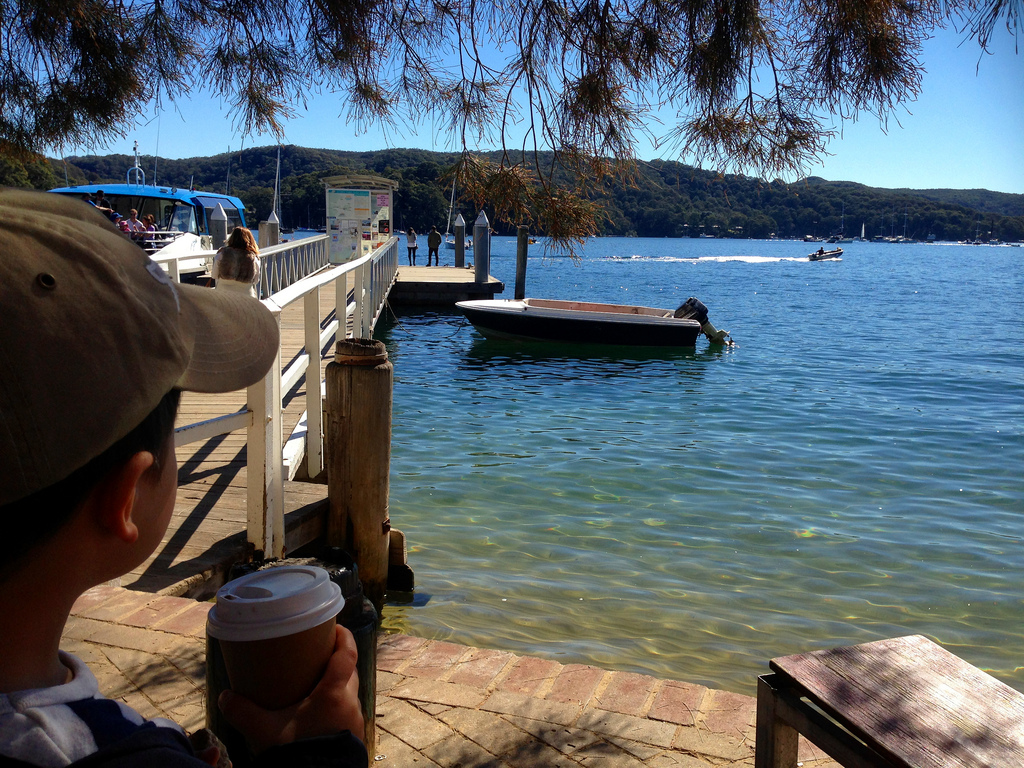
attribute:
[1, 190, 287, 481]
cap — baseball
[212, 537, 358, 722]
cup — coffee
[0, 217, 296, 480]
cap — brown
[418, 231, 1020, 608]
water — dark blue, dark, blue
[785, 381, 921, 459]
ripples — blue, dark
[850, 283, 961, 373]
ripples — dark, blue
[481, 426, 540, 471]
ripples — blue, dark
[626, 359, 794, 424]
ripples — dark, blue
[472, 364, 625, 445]
ripples — blue, dark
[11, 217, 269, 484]
hat — faded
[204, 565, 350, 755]
cup — cardboard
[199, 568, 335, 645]
lid — white, plastic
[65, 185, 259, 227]
tarp — blue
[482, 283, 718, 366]
boat — empty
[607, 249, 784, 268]
wake — white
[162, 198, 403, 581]
fence — white, wooden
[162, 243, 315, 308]
fence — wooden, white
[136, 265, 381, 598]
dock — brown, wooden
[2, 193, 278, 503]
baseball hat — tan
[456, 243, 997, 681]
water — small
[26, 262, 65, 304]
hole — metal